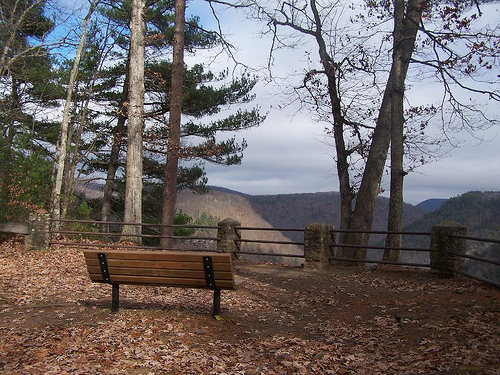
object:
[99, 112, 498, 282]
view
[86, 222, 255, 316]
point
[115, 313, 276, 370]
leaves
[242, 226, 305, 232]
railings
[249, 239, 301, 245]
railings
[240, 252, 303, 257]
railings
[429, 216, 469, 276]
stone rock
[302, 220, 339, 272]
stone rock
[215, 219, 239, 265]
stone rock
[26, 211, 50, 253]
stone rock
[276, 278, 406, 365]
leaves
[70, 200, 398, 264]
fence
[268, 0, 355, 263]
trees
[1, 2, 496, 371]
park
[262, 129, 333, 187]
cloud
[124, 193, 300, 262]
hills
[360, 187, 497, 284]
mountain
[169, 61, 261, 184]
branches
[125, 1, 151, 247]
tree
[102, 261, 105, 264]
screws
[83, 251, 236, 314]
bench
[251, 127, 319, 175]
blue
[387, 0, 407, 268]
trees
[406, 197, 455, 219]
mountains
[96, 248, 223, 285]
plates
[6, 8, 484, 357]
photo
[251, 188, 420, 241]
mountains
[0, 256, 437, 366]
ground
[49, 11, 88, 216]
trees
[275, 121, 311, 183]
sky